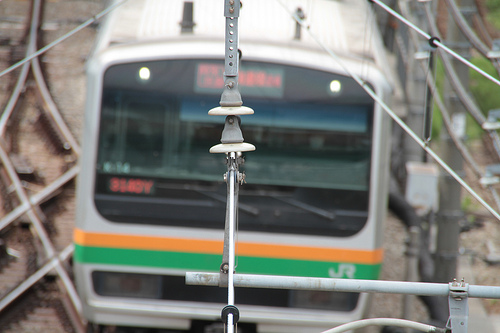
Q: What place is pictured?
A: It is a station.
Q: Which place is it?
A: It is a station.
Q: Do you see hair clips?
A: No, there are no hair clips.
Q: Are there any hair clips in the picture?
A: No, there are no hair clips.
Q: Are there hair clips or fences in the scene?
A: No, there are no hair clips or fences.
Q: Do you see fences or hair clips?
A: No, there are no hair clips or fences.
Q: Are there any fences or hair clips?
A: No, there are no hair clips or fences.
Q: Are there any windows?
A: Yes, there is a window.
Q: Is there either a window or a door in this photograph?
A: Yes, there is a window.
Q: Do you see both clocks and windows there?
A: No, there is a window but no clocks.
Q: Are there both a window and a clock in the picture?
A: No, there is a window but no clocks.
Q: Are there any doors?
A: No, there are no doors.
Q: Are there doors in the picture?
A: No, there are no doors.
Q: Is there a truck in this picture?
A: No, there are no trucks.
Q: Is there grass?
A: Yes, there is grass.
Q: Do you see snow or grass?
A: Yes, there is grass.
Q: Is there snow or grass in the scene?
A: Yes, there is grass.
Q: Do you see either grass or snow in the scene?
A: Yes, there is grass.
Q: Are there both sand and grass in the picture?
A: No, there is grass but no sand.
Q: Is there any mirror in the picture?
A: No, there are no mirrors.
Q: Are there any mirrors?
A: No, there are no mirrors.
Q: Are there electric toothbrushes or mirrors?
A: No, there are no mirrors or electric toothbrushes.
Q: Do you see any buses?
A: Yes, there is a bus.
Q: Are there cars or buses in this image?
A: Yes, there is a bus.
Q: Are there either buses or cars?
A: Yes, there is a bus.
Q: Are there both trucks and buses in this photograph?
A: No, there is a bus but no trucks.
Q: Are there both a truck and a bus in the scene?
A: No, there is a bus but no trucks.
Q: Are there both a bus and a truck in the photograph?
A: No, there is a bus but no trucks.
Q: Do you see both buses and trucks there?
A: No, there is a bus but no trucks.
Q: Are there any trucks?
A: No, there are no trucks.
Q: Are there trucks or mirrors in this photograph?
A: No, there are no trucks or mirrors.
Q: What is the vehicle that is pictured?
A: The vehicle is a bus.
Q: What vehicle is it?
A: The vehicle is a bus.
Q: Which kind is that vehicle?
A: This is a bus.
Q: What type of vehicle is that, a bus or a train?
A: This is a bus.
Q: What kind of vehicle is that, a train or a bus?
A: This is a bus.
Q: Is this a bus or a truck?
A: This is a bus.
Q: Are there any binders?
A: No, there are no binders.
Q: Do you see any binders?
A: No, there are no binders.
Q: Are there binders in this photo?
A: No, there are no binders.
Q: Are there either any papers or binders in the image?
A: No, there are no binders or papers.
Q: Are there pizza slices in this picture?
A: No, there are no pizza slices.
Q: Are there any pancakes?
A: No, there are no pancakes.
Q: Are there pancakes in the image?
A: No, there are no pancakes.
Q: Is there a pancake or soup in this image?
A: No, there are no pancakes or soup.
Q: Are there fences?
A: No, there are no fences.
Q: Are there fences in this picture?
A: No, there are no fences.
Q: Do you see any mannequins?
A: No, there are no mannequins.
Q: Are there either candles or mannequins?
A: No, there are no mannequins or candles.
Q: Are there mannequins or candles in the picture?
A: No, there are no mannequins or candles.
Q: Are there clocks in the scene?
A: No, there are no clocks.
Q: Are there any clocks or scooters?
A: No, there are no clocks or scooters.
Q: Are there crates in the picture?
A: No, there are no crates.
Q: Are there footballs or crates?
A: No, there are no crates or footballs.